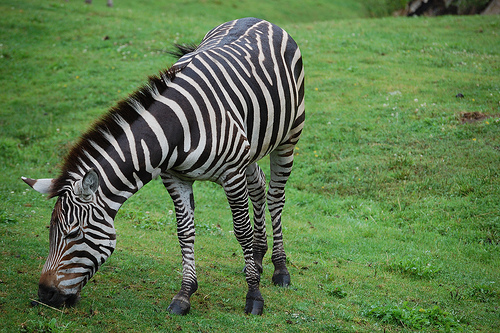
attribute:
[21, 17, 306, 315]
zebra — black and white, grazing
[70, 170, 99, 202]
pointy ear — grey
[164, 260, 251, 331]
hooves — black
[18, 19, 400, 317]
zebra — black and white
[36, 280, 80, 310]
nose — black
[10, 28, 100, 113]
grass — green, short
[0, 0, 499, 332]
grass — green, short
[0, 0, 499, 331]
ground — slightly sloped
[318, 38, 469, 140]
grass — brown, short, green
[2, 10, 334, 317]
zebra — black and white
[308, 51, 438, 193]
grass — short, green, brown